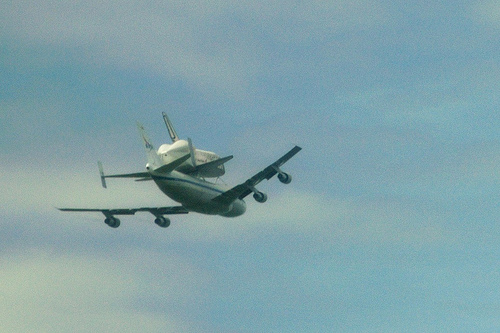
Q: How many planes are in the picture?
A: Two.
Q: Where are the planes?
A: In the sky.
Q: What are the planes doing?
A: Flying.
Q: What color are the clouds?
A: White.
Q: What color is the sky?
A: Blue.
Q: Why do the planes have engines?
A: So they can fly.